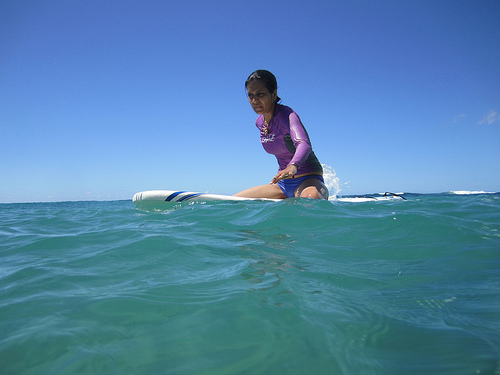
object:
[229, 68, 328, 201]
woman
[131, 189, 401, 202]
surfboard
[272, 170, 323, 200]
bikini bottoms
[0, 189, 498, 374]
ocean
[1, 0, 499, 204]
sky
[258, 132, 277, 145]
writing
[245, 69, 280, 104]
hair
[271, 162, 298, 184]
hand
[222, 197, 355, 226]
wave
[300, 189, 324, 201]
knee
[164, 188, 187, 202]
stripes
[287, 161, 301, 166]
wrist watch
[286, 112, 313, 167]
arm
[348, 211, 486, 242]
waves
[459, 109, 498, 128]
cloud